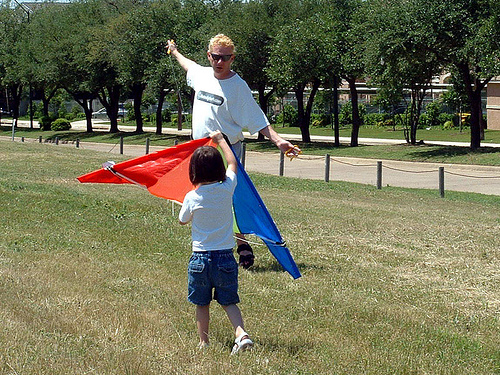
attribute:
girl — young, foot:
[176, 140, 272, 373]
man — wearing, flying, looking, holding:
[114, 22, 340, 137]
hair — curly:
[204, 27, 234, 48]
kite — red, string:
[70, 120, 190, 222]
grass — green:
[2, 195, 103, 260]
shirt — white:
[172, 181, 269, 260]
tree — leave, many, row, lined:
[325, 22, 457, 168]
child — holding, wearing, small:
[137, 165, 270, 331]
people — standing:
[106, 14, 339, 298]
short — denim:
[161, 255, 245, 308]